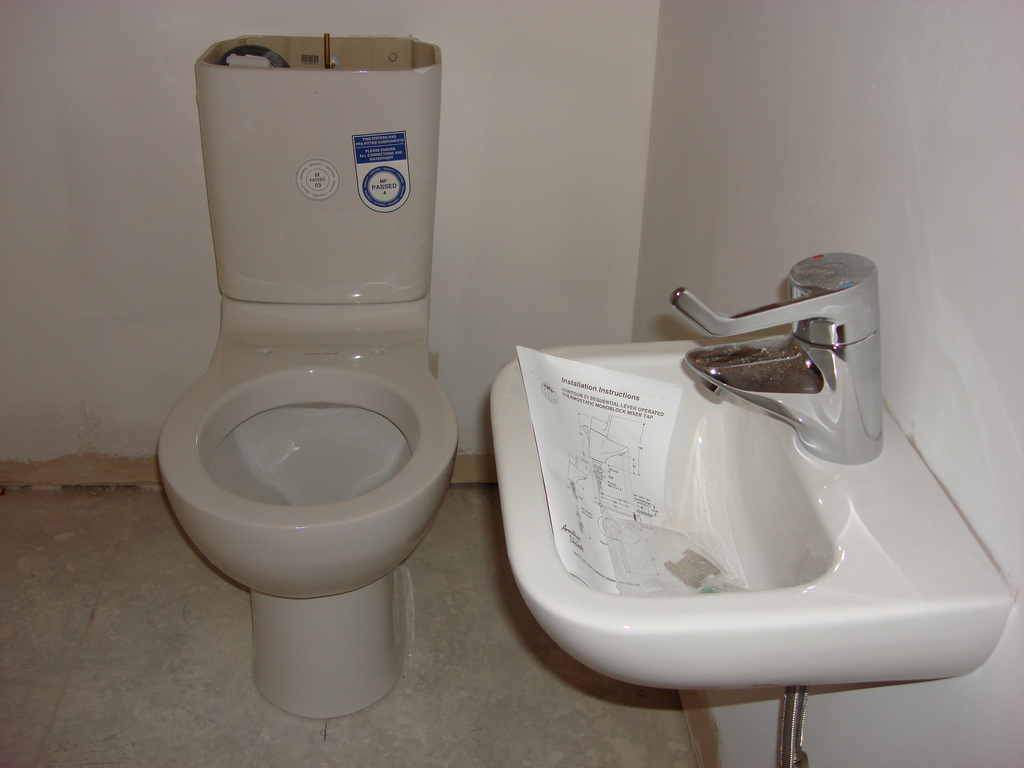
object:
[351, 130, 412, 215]
label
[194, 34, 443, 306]
tank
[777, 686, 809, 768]
pipe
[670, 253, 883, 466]
water faucet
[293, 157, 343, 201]
sticker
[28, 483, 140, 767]
line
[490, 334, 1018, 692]
bathroom sink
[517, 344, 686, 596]
instruction book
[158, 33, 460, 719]
toilet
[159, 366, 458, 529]
bowl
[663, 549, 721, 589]
item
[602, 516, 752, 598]
cover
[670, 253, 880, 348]
handle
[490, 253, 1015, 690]
sink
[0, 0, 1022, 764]
bathroom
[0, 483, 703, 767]
floor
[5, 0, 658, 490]
wall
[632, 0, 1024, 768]
wall